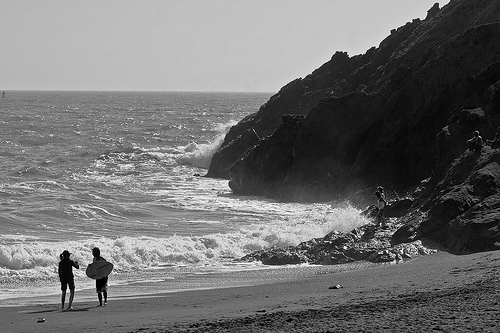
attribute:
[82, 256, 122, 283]
board — surf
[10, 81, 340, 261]
body — large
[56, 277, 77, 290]
pant — short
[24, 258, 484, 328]
beach — sandy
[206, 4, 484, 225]
rocks — black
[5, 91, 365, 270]
body — water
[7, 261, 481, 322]
beach — sandy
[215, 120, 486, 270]
shore — rocky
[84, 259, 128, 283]
surfboard — white